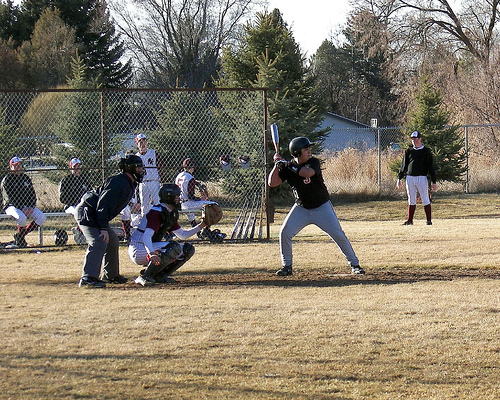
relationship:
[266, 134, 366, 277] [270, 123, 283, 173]
player holding bat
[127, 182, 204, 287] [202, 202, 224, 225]
catcher has mit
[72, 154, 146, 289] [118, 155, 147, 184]
umpire has helmet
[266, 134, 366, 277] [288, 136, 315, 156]
player has helmet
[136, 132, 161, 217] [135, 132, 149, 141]
player has hat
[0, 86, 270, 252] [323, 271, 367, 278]
fence behind base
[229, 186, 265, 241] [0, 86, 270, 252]
bats leaning on fence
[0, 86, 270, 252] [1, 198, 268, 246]
fence covering dugout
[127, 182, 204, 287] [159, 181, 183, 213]
catcher has mask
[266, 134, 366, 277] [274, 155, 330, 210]
player wearing shirt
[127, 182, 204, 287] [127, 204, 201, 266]
catcher wearing uniform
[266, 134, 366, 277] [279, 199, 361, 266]
player wearing pants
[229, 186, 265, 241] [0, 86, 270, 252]
bats learning against fence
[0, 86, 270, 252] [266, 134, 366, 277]
fence behind player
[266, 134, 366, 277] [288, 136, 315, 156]
player wearing helmet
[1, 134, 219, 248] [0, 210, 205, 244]
people sitting on bench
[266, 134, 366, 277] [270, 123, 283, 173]
player has bat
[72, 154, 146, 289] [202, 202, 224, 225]
umpire holding up mit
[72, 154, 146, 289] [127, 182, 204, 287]
referee behind umpire